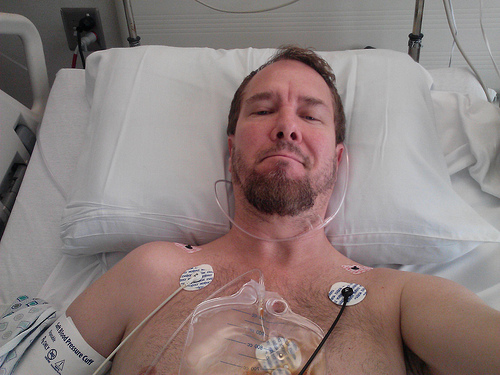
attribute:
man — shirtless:
[25, 56, 499, 374]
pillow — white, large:
[85, 43, 470, 267]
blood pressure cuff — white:
[16, 317, 111, 373]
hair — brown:
[224, 50, 344, 133]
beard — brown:
[228, 147, 339, 217]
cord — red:
[68, 49, 82, 70]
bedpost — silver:
[407, 3, 426, 57]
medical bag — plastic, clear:
[195, 283, 328, 373]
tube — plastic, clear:
[163, 265, 263, 374]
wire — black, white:
[281, 287, 367, 374]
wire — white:
[80, 271, 209, 375]